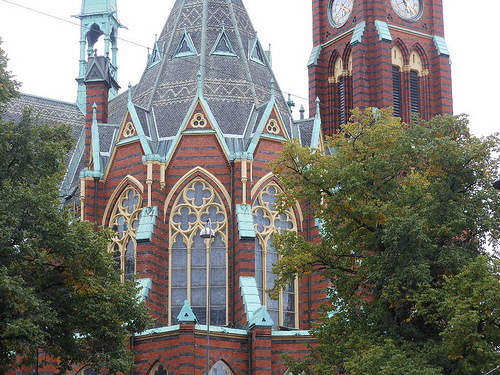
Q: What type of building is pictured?
A: A church.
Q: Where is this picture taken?
A: A city.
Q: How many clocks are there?
A: Two.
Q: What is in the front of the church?
A: Trees.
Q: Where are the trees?
A: In the front of the church.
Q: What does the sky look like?
A: Overcast.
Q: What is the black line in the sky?
A: A powerline.